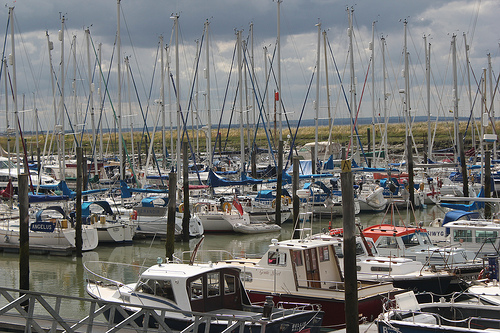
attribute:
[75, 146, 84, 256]
pole — wooden, long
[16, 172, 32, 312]
pole — wooden, long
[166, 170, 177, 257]
pole — wooden, long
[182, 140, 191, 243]
pole — wooden, long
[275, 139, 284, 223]
pole — wooden, long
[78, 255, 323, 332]
boat — brown, small, white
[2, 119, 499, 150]
field — grassy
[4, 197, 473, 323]
water — brownish green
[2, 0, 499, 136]
sky — cloudy, dark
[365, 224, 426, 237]
roof — red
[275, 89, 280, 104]
flag — small, red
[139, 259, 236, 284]
roof — white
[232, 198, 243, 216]
flag — red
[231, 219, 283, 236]
dingy — inflatable